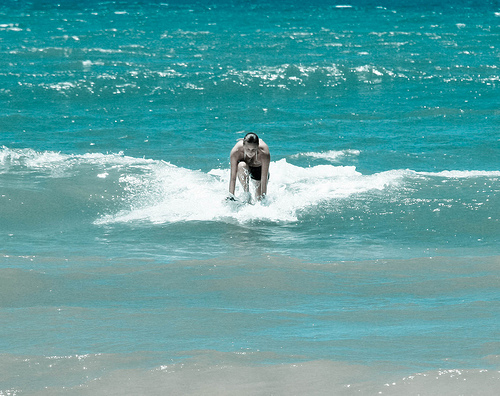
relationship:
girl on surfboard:
[222, 128, 275, 204] [221, 199, 274, 210]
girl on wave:
[222, 128, 275, 204] [44, 134, 403, 249]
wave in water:
[44, 134, 403, 249] [25, 69, 447, 217]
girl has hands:
[222, 128, 275, 204] [224, 180, 240, 215]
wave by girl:
[44, 134, 403, 249] [209, 114, 313, 224]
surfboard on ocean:
[221, 199, 274, 210] [293, 195, 461, 362]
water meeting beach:
[25, 69, 447, 217] [10, 342, 480, 395]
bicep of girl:
[260, 154, 274, 181] [222, 128, 275, 204]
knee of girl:
[232, 158, 263, 180] [222, 128, 275, 204]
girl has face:
[222, 128, 275, 204] [241, 132, 266, 154]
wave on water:
[44, 134, 403, 249] [25, 69, 447, 217]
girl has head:
[222, 128, 275, 204] [236, 129, 273, 153]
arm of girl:
[220, 141, 243, 197] [222, 128, 275, 204]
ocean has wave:
[293, 195, 461, 362] [44, 134, 403, 249]